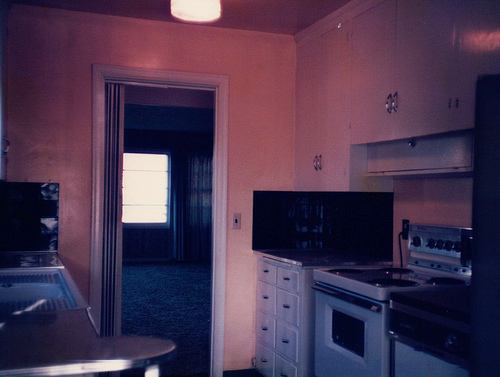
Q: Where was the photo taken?
A: In a kitchen.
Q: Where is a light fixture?
A: On the ceiling.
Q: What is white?
A: Oven.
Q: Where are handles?
A: On cabinets.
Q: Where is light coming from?
A: A window.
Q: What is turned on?
A: A light.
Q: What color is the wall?
A: Beige.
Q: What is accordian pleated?
A: The door.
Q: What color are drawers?
A: White.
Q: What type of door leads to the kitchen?
A: Folding door.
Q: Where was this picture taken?
A: Kitchen.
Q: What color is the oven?
A: White.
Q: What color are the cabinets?
A: White.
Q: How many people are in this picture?
A: Zero.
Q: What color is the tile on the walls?
A: Black.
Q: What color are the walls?
A: Tan.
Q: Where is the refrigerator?
A: On the right.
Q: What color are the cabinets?
A: Tan.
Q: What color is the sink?
A: Silver.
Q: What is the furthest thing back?
A: A Window.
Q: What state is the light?
A: On.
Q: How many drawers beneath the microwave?
A: 8.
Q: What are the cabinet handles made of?
A: Metal.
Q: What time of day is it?
A: Daytime.